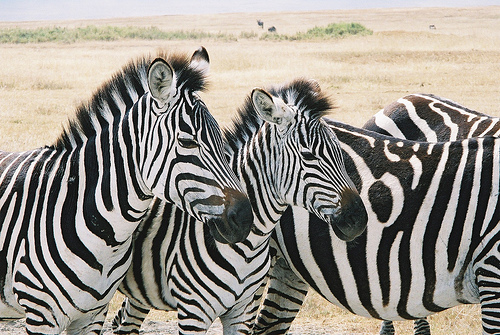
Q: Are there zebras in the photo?
A: Yes, there is a zebra.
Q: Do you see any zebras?
A: Yes, there is a zebra.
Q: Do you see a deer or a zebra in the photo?
A: Yes, there is a zebra.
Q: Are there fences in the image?
A: No, there are no fences.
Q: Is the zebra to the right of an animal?
A: Yes, the zebra is to the right of an animal.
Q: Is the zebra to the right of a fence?
A: No, the zebra is to the right of an animal.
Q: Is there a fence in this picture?
A: No, there are no fences.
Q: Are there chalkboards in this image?
A: No, there are no chalkboards.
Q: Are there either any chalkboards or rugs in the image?
A: No, there are no chalkboards or rugs.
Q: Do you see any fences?
A: No, there are no fences.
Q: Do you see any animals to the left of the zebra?
A: Yes, there is an animal to the left of the zebra.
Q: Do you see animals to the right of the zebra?
A: No, the animal is to the left of the zebra.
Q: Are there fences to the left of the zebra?
A: No, there is an animal to the left of the zebra.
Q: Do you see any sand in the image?
A: Yes, there is sand.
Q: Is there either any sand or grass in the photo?
A: Yes, there is sand.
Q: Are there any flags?
A: No, there are no flags.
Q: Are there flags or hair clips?
A: No, there are no flags or hair clips.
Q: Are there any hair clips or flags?
A: No, there are no flags or hair clips.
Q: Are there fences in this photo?
A: No, there are no fences.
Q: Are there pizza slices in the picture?
A: No, there are no pizza slices.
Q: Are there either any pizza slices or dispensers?
A: No, there are no pizza slices or dispensers.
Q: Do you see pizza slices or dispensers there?
A: No, there are no pizza slices or dispensers.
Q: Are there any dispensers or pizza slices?
A: No, there are no pizza slices or dispensers.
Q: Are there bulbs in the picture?
A: No, there are no bulbs.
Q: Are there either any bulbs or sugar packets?
A: No, there are no bulbs or sugar packets.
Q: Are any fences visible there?
A: No, there are no fences.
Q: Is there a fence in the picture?
A: No, there are no fences.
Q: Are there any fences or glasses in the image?
A: No, there are no fences or glasses.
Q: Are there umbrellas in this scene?
A: No, there are no umbrellas.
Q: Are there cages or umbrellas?
A: No, there are no umbrellas or cages.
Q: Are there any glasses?
A: No, there are no glasses.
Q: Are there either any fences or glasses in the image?
A: No, there are no glasses or fences.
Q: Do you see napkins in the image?
A: No, there are no napkins.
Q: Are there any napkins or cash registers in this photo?
A: No, there are no napkins or cash registers.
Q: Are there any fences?
A: No, there are no fences.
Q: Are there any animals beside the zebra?
A: Yes, there is an animal beside the zebra.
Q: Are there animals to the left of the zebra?
A: Yes, there is an animal to the left of the zebra.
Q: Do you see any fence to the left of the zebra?
A: No, there is an animal to the left of the zebra.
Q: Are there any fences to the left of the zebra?
A: No, there is an animal to the left of the zebra.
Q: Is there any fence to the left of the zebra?
A: No, there is an animal to the left of the zebra.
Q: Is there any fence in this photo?
A: No, there are no fences.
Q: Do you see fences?
A: No, there are no fences.